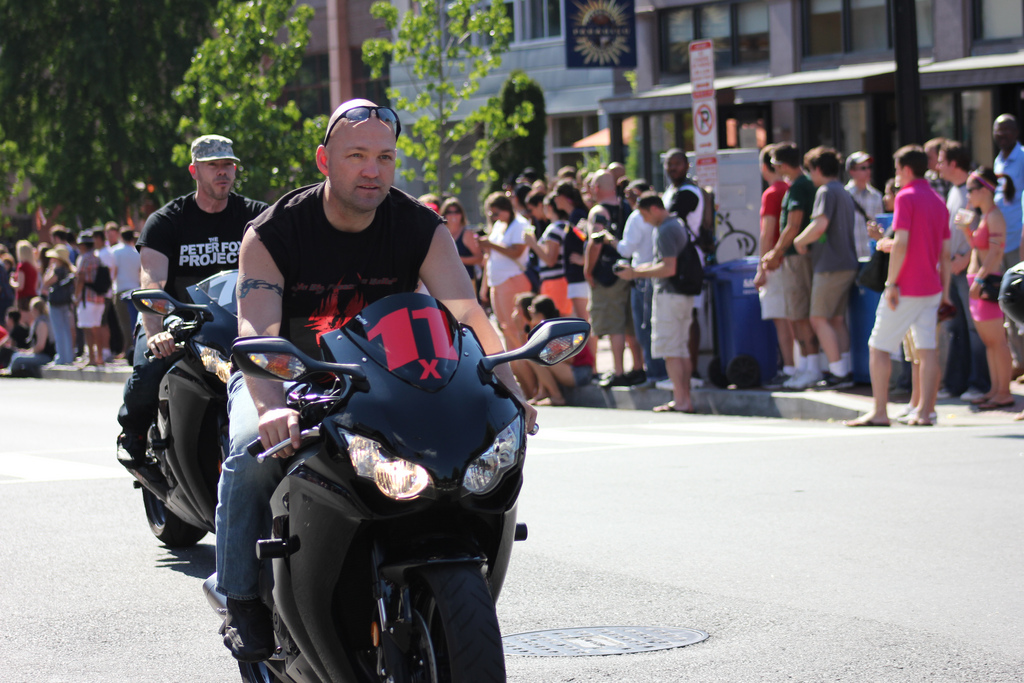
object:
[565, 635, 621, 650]
manhole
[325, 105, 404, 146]
sunglasses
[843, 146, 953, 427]
man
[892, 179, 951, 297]
shirt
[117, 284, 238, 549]
motorcycle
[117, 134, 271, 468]
man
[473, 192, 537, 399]
people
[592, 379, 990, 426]
sidewalk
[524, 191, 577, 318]
woman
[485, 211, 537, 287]
top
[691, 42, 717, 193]
signs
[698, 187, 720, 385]
pole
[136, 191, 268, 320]
shirt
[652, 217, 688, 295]
shirt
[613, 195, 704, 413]
man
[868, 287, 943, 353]
shorts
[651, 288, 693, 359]
shorts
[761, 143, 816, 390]
man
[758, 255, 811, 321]
shorts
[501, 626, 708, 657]
manhole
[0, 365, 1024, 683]
ground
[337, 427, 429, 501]
headlights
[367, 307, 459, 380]
number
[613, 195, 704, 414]
people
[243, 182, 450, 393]
shirt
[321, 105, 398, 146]
glasses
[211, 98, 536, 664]
man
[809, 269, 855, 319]
shorts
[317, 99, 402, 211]
head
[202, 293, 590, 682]
motorcycle